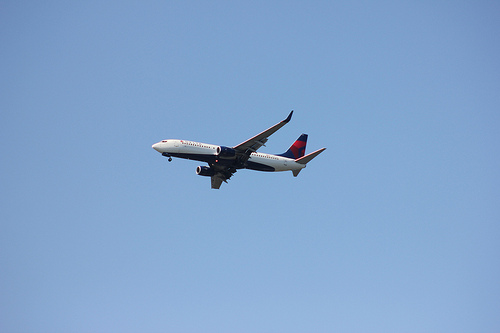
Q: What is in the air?
A: A plane.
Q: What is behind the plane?
A: The sky.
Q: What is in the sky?
A: A plane.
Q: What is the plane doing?
A: Flying.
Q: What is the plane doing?
A: Flying.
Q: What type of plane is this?
A: A passenger plane.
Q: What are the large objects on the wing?
A: The engines.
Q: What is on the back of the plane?
A: The tail.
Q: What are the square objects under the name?
A: The passenger windows.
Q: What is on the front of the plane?
A: The cockpit.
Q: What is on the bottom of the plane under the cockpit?
A: The front landing gear.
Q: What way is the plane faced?
A: The left.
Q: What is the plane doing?
A: Flying in the air.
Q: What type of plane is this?
A: A jet plane.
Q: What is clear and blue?
A: The sky.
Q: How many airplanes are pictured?
A: One.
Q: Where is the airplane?
A: In the sky.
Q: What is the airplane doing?
A: Flying.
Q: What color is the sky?
A: Blue.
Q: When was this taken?
A: During the day.